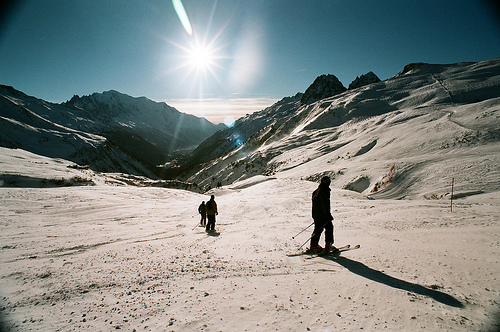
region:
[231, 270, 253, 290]
Small patch of snow on the ground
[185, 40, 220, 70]
Bright sun in the sky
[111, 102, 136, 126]
Mountain in the background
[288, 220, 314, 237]
Left ski pole of the skier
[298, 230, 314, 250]
Right ski pole of the skier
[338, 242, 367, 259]
Skis of the skier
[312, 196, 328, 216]
Dark jacket of the male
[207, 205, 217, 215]
Yellow jacket of the skier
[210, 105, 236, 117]
White clouds in the sky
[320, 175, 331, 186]
Hat of the skier in the front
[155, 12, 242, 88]
Sun is in the sky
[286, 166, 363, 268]
A person is skiing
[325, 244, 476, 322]
Person is casting a shadow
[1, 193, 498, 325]
Gound is covered in snow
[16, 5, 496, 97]
The sky is clear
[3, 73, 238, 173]
Mountains are in the background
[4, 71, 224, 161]
Mountains are snow covered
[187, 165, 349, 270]
Three people are in the photo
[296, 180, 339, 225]
Person is wearing a coat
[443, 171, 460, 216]
A pole is in the background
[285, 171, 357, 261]
Skiier on the mountain.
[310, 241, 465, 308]
Shadow of the skiier on the mountain.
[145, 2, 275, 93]
Sun shining brightly in the sky.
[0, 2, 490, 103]
Beautiful blue sky up high.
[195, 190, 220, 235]
Two other skiiers on the mountain.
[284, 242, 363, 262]
Skis on the skiier.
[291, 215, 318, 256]
Ski poles used by the skiier.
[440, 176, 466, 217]
Pole on the mountain.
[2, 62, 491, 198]
Majestic mountains in the background.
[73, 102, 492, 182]
Trees on the mountain.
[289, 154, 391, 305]
A person on skis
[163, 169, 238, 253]
Two people on skis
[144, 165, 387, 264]
Three people on skis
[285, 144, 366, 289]
A person holding ski poles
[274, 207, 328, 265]
Two ski poles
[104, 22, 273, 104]
A bright sun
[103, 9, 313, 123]
The sun is a clear sky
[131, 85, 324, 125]
The horizon in the distance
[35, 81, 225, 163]
A mountain in the distance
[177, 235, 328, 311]
Snow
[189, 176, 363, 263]
three skiers in snow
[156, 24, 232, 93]
bright sun is shining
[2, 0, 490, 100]
a clear bright blue sky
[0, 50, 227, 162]
rocky mountains in the distance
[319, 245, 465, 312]
shadow in the snow of skier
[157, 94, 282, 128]
clouds between the mountains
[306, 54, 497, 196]
snow covered hill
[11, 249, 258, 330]
rough snow covered terrain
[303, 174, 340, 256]
skier all in black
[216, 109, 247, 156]
glare on camera lens